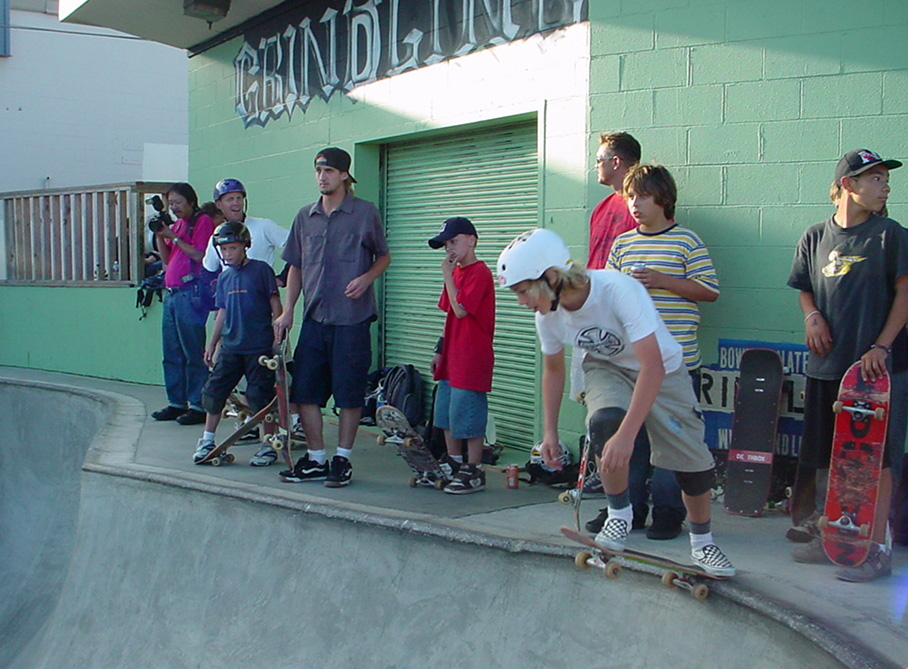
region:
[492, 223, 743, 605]
boy is wearing a white helmet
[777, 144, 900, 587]
boy is holding a red skateboard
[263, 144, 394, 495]
guy is wearing a black cap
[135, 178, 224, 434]
guy in a pink shirt is taking a photograph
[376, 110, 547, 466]
green painted roller shutter door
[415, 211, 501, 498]
young boy in a red shirt has his hand to his mouth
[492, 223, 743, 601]
skateboarder wears black and white shoes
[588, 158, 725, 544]
boy in a striped shirt is watching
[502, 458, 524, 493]
orange soda can is on the ground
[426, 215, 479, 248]
Black hat on a kid.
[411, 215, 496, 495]
A boy in a black hat and red shirt.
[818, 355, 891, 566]
A red skateboard with black letters on it.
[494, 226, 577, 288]
White helmet on a kid on a skateboard.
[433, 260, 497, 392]
Red shirt on a boy.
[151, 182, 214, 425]
Black haired man in a pink shirt.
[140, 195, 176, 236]
Black camera in a pink shirt mans hand.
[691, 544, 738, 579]
A checkered left shoe on a skateboard.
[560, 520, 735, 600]
Skateboard with two black and white checkered shoes on top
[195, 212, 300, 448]
a person walking on a sidewalk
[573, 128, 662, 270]
a person walking on a sidewalk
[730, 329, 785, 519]
skateboard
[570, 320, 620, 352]
large white cross on white shirt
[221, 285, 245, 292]
small orange detail on blue shirt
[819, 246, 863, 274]
small white and yellow detail on black shirt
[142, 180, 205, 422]
man in red shirt holds black camera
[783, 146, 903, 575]
teen boy in black shirt wears black cap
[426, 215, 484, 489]
young boy in black cap wears red shirt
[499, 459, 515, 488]
small red and white Coca Cola can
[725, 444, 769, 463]
red and white rectangular sticker on black skateboard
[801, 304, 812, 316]
small white bracelet on right wrist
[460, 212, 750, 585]
a person is playing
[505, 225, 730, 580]
a person is standing up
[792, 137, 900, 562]
a person is standing up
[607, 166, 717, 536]
a person is standing up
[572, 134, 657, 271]
a person is standing up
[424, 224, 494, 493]
a person is standing up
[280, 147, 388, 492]
a person is standing up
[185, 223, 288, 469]
a person is standing up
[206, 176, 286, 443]
a person is standing up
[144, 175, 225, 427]
a person is standing up